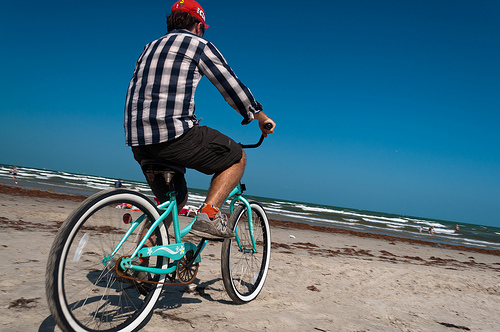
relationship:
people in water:
[407, 222, 469, 242] [322, 205, 352, 218]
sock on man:
[202, 201, 219, 221] [131, 0, 278, 271]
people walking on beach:
[5, 162, 122, 194] [0, 161, 498, 330]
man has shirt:
[120, 0, 276, 240] [121, 31, 263, 148]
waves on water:
[4, 165, 457, 236] [2, 162, 499, 252]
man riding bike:
[120, 0, 276, 240] [45, 119, 271, 330]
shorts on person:
[125, 130, 241, 189] [117, 7, 280, 294]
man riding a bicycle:
[139, 3, 256, 237] [54, 164, 301, 319]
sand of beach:
[271, 252, 498, 329] [314, 148, 471, 315]